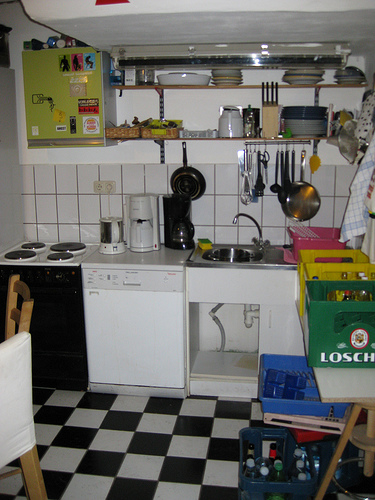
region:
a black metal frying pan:
[170, 140, 207, 201]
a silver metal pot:
[278, 147, 319, 220]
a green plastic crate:
[305, 277, 373, 369]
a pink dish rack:
[282, 223, 351, 263]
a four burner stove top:
[0, 240, 99, 265]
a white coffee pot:
[97, 216, 125, 255]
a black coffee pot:
[162, 193, 195, 250]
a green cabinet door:
[23, 49, 106, 147]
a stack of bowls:
[212, 67, 244, 85]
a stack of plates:
[280, 67, 325, 85]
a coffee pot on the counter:
[93, 204, 137, 267]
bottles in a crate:
[218, 413, 305, 488]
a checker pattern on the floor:
[61, 409, 192, 496]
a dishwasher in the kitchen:
[70, 242, 207, 404]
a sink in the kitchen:
[215, 205, 282, 269]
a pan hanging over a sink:
[285, 145, 321, 230]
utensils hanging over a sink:
[238, 141, 283, 220]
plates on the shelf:
[280, 92, 334, 143]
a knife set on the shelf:
[256, 79, 283, 142]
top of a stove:
[12, 227, 81, 269]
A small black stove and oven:
[0, 236, 101, 396]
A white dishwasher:
[78, 239, 197, 402]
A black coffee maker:
[154, 184, 199, 256]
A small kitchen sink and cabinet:
[179, 210, 311, 404]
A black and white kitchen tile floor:
[1, 376, 271, 497]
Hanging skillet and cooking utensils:
[236, 140, 327, 225]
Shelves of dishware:
[102, 42, 372, 144]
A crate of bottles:
[227, 418, 342, 498]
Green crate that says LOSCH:
[301, 276, 374, 369]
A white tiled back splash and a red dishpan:
[4, 160, 369, 263]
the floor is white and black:
[40, 329, 187, 496]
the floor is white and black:
[98, 405, 181, 496]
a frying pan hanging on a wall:
[165, 141, 202, 194]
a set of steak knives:
[253, 78, 284, 135]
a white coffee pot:
[125, 180, 164, 251]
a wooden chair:
[0, 275, 32, 339]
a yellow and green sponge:
[193, 232, 215, 266]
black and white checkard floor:
[98, 408, 209, 471]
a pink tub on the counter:
[282, 218, 346, 261]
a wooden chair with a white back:
[0, 324, 36, 475]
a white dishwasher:
[63, 255, 187, 372]